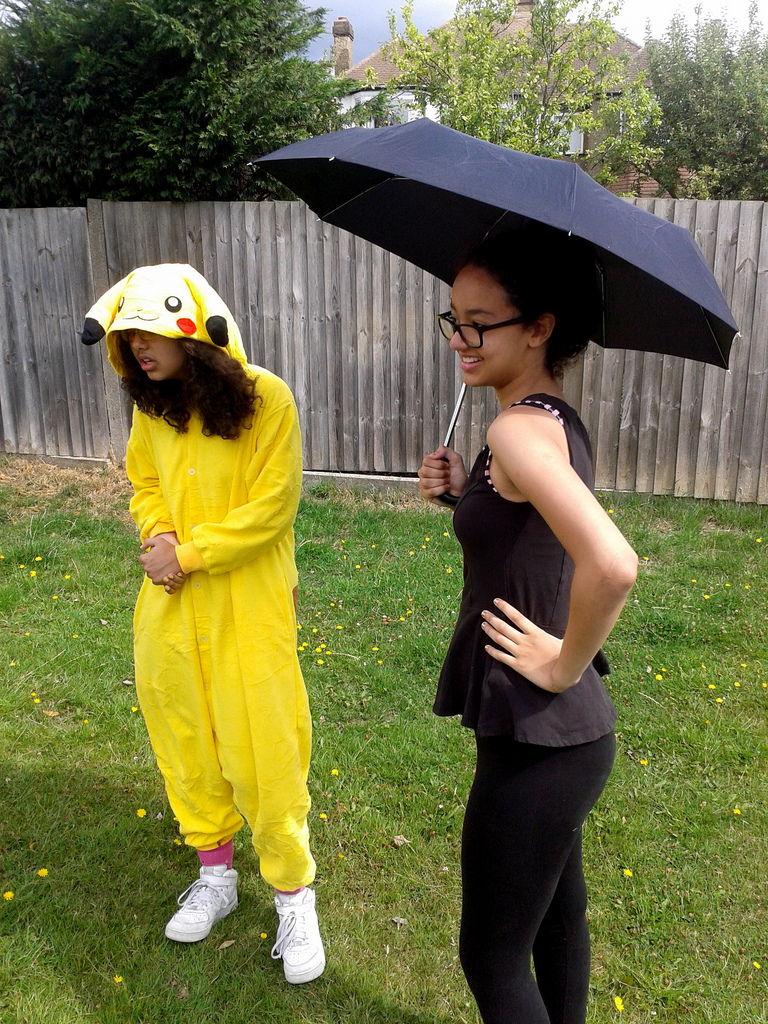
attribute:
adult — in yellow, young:
[68, 258, 345, 997]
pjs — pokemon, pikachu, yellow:
[69, 255, 327, 904]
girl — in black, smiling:
[409, 239, 660, 1023]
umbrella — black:
[238, 107, 754, 385]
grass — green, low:
[2, 457, 768, 1023]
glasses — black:
[436, 305, 536, 346]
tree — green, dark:
[2, 1, 373, 217]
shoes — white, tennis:
[266, 891, 339, 991]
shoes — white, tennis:
[159, 867, 249, 944]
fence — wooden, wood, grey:
[2, 178, 768, 511]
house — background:
[306, 3, 723, 198]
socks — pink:
[183, 839, 239, 877]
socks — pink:
[267, 880, 323, 901]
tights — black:
[444, 711, 622, 1023]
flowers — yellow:
[127, 806, 149, 826]